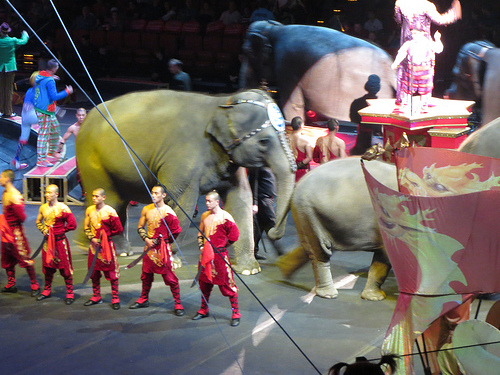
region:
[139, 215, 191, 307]
THE CLOTHES ARE RED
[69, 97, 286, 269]
the elephant is grey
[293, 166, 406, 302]
the elephant is grey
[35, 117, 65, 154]
the pants are green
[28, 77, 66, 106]
the top is blue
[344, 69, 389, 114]
shadow is onthe elephant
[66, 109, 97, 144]
the man is shirtless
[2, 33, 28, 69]
the shirt is green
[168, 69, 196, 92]
the man is in a black suit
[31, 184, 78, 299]
the man is bald heaaded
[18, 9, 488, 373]
scene at a circus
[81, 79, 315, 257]
elephant in a circus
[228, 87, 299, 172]
decoration on elephant's head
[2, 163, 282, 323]
male acrobats on the ground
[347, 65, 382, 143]
shadow casted on an elephant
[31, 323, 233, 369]
flooring at a circus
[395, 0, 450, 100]
people standing on a platform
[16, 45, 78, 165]
clowns on a platform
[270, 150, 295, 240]
trunk of an elephant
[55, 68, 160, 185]
wires suspended at a circus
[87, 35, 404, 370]
view is at a museum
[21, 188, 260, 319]
the woriors are in order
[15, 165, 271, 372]
wot9irs aere dressed in same outfit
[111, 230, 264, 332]
both are holding aweapon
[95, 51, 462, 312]
the elepahnts are behind the woariors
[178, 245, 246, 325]
the outfit is red in color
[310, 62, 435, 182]
light shines through the elepanhts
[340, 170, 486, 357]
the cloth is red white in color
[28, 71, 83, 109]
the jacket is blue incolor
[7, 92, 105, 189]
man is standing on the tables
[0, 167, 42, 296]
circus performer on stage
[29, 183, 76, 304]
circus performer on stage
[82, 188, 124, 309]
circus performer on stage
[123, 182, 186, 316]
circus performer on stage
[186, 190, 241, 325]
circus performer on stage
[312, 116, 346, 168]
circus performer on stage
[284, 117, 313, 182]
circus performer on stage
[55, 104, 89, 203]
circus performer on stage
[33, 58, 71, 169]
circus performer on stage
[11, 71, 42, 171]
circus performer on stage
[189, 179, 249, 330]
person at the circus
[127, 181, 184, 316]
person at the circus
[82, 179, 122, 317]
person at the circus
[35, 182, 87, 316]
person at the circus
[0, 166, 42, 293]
person at the circus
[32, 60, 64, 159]
person at the circus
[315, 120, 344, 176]
person at the circus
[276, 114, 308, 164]
person at the circus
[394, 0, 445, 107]
person at the circus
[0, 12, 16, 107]
person at the circus